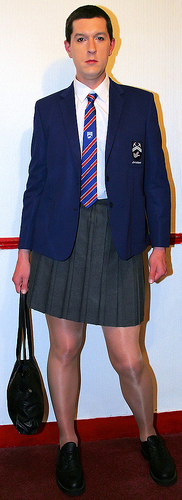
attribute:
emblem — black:
[130, 141, 143, 164]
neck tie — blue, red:
[79, 91, 99, 210]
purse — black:
[4, 292, 48, 432]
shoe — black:
[52, 433, 84, 494]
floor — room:
[5, 415, 170, 490]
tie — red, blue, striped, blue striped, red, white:
[80, 91, 100, 207]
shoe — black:
[136, 428, 175, 484]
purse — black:
[5, 279, 40, 436]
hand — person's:
[11, 259, 31, 293]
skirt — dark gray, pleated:
[18, 198, 146, 331]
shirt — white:
[73, 76, 109, 205]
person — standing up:
[4, 4, 173, 498]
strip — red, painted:
[2, 232, 176, 250]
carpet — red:
[5, 413, 172, 495]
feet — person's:
[54, 422, 173, 492]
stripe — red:
[88, 93, 93, 99]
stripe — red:
[84, 115, 96, 129]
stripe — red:
[81, 160, 96, 179]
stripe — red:
[78, 148, 95, 166]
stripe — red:
[81, 182, 95, 197]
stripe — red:
[82, 138, 95, 155]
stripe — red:
[84, 192, 98, 204]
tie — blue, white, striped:
[78, 93, 101, 207]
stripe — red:
[85, 101, 90, 107]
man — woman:
[12, 1, 175, 485]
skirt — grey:
[48, 194, 152, 326]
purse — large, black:
[4, 278, 55, 439]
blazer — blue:
[20, 78, 168, 244]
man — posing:
[57, 16, 135, 167]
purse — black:
[5, 272, 46, 434]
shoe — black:
[43, 430, 181, 499]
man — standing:
[61, 2, 123, 101]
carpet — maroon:
[24, 430, 167, 468]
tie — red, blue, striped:
[77, 91, 113, 217]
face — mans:
[70, 13, 128, 70]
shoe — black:
[50, 431, 173, 498]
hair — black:
[55, 4, 131, 39]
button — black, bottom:
[100, 195, 125, 220]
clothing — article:
[20, 199, 147, 329]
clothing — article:
[77, 90, 103, 209]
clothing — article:
[14, 76, 174, 263]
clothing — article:
[101, 323, 159, 437]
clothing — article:
[70, 75, 111, 201]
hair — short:
[61, 0, 115, 45]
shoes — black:
[52, 430, 178, 498]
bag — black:
[5, 283, 52, 437]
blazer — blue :
[20, 67, 173, 258]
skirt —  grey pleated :
[20, 203, 156, 324]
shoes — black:
[45, 425, 177, 496]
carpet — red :
[96, 433, 141, 482]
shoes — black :
[48, 417, 177, 492]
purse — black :
[7, 280, 46, 438]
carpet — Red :
[99, 443, 131, 477]